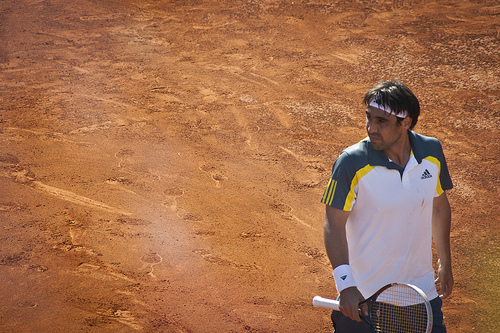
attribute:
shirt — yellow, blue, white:
[296, 70, 452, 331]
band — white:
[331, 262, 357, 292]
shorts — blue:
[328, 288, 448, 331]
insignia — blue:
[418, 166, 434, 180]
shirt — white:
[317, 128, 452, 307]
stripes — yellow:
[306, 143, 413, 245]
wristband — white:
[327, 262, 360, 298]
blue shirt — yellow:
[309, 118, 439, 195]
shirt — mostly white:
[250, 37, 473, 314]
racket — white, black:
[310, 282, 434, 332]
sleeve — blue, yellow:
[320, 151, 354, 210]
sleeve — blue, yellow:
[435, 133, 452, 198]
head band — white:
[363, 90, 406, 121]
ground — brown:
[1, 0, 498, 330]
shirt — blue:
[315, 126, 462, 304]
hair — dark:
[363, 80, 420, 131]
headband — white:
[368, 97, 406, 117]